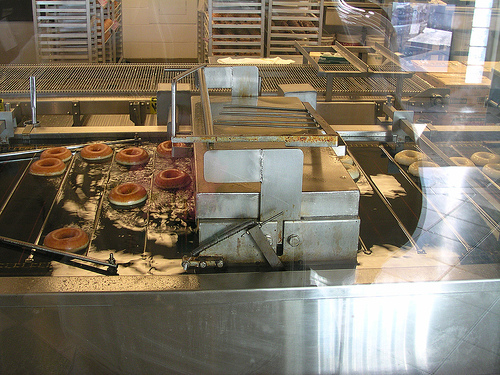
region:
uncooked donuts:
[387, 134, 457, 195]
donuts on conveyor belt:
[44, 147, 193, 253]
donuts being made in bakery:
[23, 95, 411, 262]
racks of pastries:
[196, 4, 341, 52]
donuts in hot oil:
[26, 152, 179, 247]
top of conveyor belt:
[23, 57, 150, 104]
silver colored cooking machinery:
[129, 73, 396, 295]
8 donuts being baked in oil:
[26, 146, 191, 258]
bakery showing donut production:
[268, 19, 491, 261]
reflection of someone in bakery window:
[271, 9, 498, 164]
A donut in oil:
[105, 177, 152, 211]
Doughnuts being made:
[378, 139, 435, 170]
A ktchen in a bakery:
[62, 19, 451, 202]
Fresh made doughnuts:
[21, 132, 190, 245]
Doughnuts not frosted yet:
[34, 142, 67, 174]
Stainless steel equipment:
[193, 280, 331, 372]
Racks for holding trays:
[36, 4, 99, 64]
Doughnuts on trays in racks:
[216, 0, 263, 50]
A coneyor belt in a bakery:
[1, 59, 147, 96]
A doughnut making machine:
[235, 101, 447, 266]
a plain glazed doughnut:
[27, 158, 66, 177]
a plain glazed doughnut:
[37, 145, 72, 161]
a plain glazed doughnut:
[79, 140, 113, 161]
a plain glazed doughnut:
[114, 145, 146, 168]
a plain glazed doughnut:
[156, 138, 184, 157]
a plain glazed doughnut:
[153, 165, 190, 190]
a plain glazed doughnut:
[106, 183, 144, 206]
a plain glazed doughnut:
[42, 226, 89, 253]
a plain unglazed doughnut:
[394, 145, 426, 163]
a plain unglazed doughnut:
[405, 159, 437, 177]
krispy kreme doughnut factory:
[6, 10, 489, 330]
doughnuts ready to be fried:
[397, 140, 493, 206]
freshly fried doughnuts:
[30, 140, 181, 241]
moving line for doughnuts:
[5, 55, 420, 90]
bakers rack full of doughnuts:
[200, 0, 260, 65]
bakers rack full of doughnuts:
[270, 0, 315, 55]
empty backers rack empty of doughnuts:
[25, 0, 90, 60]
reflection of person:
[226, 6, 422, 262]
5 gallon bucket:
[335, 30, 360, 66]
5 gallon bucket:
[367, 33, 386, 73]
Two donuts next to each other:
[33, 149, 67, 172]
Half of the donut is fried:
[111, 178, 147, 208]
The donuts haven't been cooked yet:
[391, 147, 497, 193]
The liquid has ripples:
[153, 195, 193, 235]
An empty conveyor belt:
[52, 62, 158, 89]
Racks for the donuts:
[208, 3, 263, 56]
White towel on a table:
[219, 55, 293, 62]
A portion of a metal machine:
[173, 71, 355, 275]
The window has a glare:
[383, 8, 495, 123]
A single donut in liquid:
[48, 221, 88, 258]